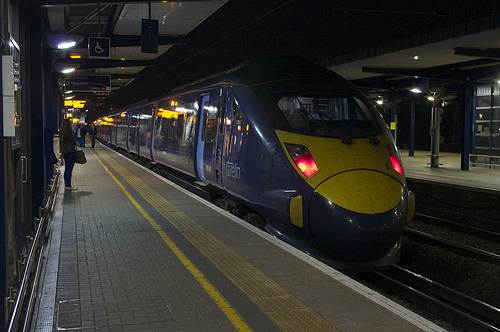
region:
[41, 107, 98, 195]
Woman waiting to board the train.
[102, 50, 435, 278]
Yellow and blue subway train.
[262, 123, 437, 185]
Read headlights of a subway train.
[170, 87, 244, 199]
Side door of a subway train where people enter and exit the train.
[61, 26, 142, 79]
Handicapped sign showing where those with a handicap can board the subway train.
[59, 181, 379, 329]
Sidewalk area where people cross to enter and exit the subway train.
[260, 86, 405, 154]
Front windshield of subway train.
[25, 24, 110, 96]
Lights that illuminate subway station.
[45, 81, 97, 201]
Woman wearing green jacket, jeans, and holding a brown purse.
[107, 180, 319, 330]
Yellow stripes on sidewalk.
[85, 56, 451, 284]
a large train at station.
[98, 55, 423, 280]
a yellow and blue train at station.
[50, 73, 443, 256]
a train at station ready for passengers.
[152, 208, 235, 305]
yellow lines on pavement.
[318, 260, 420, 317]
white line on pavement.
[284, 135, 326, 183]
right front headlight on train.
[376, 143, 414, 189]
left front headlight on train.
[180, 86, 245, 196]
door area on train.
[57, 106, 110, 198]
people standing at train station.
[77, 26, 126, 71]
a sign at the station.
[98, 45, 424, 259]
yellow and blue train in station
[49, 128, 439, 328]
gray concrete train platform with yellow stripes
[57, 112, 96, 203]
woman standing wearing black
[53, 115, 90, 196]
woman standing holding purse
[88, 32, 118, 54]
blue and white wheelchair sign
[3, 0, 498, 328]
nighttime partially enclosed train station scene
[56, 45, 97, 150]
yellow lit lights in ceiling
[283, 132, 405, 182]
two red lit headlights on train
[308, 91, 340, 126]
man in blue shirt inside train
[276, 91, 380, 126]
conductor sitting behind train window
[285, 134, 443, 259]
the train is yellow and blue infront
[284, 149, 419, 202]
the headlights are on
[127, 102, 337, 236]
the whole train is blue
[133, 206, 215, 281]
there is a yellow line on the pavement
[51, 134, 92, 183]
the woman is waiting for the train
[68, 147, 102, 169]
she is carrying a brown bag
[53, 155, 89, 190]
her jeans is blue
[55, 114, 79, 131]
she has brown hair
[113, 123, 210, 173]
there is reflection on the train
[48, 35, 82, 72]
the lights are on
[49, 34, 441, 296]
subway or tram at a station underground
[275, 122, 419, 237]
front of train is yellow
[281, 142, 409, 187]
front of train has two red lights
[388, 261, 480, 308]
track for the train is below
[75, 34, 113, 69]
handicapped area sign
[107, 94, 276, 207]
most of the train is blue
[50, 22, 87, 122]
overhead lights in the station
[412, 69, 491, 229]
opposite side of the tracks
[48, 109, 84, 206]
person waiting for train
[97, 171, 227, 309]
yellow lines on pavement for safety